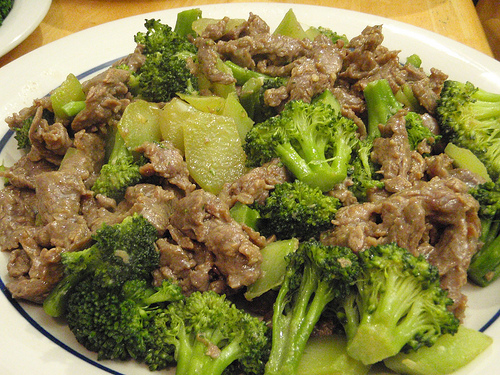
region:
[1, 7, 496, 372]
Beef and broccoli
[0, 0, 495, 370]
White dish with a blue inner ring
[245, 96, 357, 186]
A piece of cooked broccoli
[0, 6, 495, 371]
Bright green vegetables with beef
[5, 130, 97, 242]
Pieces of cooked sliced beef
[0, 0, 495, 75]
Wooden table with white plates on it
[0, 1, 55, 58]
Small section of a white dish to the side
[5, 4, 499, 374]
A white plate filled with food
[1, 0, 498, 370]
Two white plates on a light brown table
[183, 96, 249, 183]
Pieces of broccoli stalk cut up and cooked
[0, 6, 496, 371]
A plate of food.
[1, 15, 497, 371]
The plate is white.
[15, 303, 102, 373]
The plate has a blue stripe on it.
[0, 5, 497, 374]
A broccoli and beef dish on the plate.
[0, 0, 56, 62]
Another plate is partially visible.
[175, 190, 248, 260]
A chunk of beef.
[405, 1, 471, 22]
The table is made of wood.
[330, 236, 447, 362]
A piece of broccoli.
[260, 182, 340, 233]
A second piece of broccoli.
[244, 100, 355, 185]
A third piece of broccoli.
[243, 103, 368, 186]
fresh green broccoli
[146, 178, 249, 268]
fresh cook beef meat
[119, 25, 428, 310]
beef and broccoli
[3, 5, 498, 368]
beef and broccoli on plate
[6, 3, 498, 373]
food on the plate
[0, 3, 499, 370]
food on a white plate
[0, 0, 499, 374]
beef and broccoli on a round plate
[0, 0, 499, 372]
food on the table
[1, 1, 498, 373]
beef and broccoli on the table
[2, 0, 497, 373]
full plate of food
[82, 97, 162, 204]
coked green broccoli and brown meat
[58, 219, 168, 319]
coked green broccoli and brown meat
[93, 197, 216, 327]
coked green broccoli and brown meat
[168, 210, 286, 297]
coked green broccoli and brown meat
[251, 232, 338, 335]
coked green broccoli and brown meat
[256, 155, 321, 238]
coked green broccoli and brown meat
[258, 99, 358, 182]
coked green broccoli and brown meat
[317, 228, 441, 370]
coked green broccoli and brown meat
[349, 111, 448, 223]
coked green broccoli and brown meat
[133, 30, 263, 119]
coked green broccoli and brown meat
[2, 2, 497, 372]
a dish of vegetables and meat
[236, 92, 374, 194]
a piece of broccoli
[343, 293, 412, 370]
stem of broccoli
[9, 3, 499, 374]
dish is white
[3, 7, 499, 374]
a blue line around the dish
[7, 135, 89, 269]
pieces of meat on side of dish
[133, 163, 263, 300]
meat on top of broccoli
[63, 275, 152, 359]
broccoli is dark green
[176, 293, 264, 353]
broccoli is color light green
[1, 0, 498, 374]
dish on a brown table